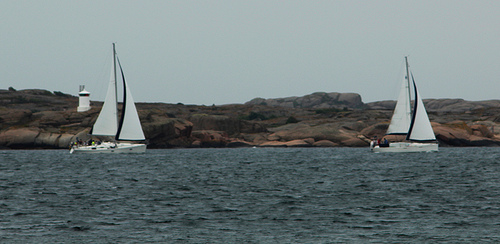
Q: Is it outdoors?
A: Yes, it is outdoors.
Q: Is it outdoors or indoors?
A: It is outdoors.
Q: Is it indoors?
A: No, it is outdoors.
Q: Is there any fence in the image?
A: No, there are no fences.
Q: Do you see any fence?
A: No, there are no fences.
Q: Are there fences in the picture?
A: No, there are no fences.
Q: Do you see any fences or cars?
A: No, there are no fences or cars.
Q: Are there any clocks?
A: No, there are no clocks.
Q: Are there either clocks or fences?
A: No, there are no clocks or fences.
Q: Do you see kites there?
A: No, there are no kites.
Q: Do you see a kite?
A: No, there are no kites.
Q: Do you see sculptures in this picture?
A: No, there are no sculptures.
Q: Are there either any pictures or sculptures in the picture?
A: No, there are no sculptures or pictures.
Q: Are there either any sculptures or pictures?
A: No, there are no sculptures or pictures.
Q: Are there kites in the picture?
A: No, there are no kites.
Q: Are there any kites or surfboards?
A: No, there are no kites or surfboards.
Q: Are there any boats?
A: Yes, there is a boat.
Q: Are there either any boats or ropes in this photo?
A: Yes, there is a boat.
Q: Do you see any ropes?
A: No, there are no ropes.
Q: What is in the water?
A: The boat is in the water.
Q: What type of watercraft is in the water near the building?
A: The watercraft is a boat.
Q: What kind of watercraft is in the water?
A: The watercraft is a boat.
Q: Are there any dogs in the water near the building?
A: No, there is a boat in the water.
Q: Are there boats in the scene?
A: Yes, there is a boat.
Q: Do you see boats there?
A: Yes, there is a boat.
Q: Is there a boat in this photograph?
A: Yes, there is a boat.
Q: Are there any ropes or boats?
A: Yes, there is a boat.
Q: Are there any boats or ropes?
A: Yes, there is a boat.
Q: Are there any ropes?
A: No, there are no ropes.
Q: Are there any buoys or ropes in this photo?
A: No, there are no ropes or buoys.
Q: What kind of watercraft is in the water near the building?
A: The watercraft is a boat.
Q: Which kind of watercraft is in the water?
A: The watercraft is a boat.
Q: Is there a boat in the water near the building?
A: Yes, there is a boat in the water.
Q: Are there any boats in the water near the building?
A: Yes, there is a boat in the water.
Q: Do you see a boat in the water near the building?
A: Yes, there is a boat in the water.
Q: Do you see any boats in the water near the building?
A: Yes, there is a boat in the water.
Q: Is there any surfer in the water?
A: No, there is a boat in the water.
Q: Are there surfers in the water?
A: No, there is a boat in the water.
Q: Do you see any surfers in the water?
A: No, there is a boat in the water.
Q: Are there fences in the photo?
A: No, there are no fences.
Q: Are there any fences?
A: No, there are no fences.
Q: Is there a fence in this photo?
A: No, there are no fences.